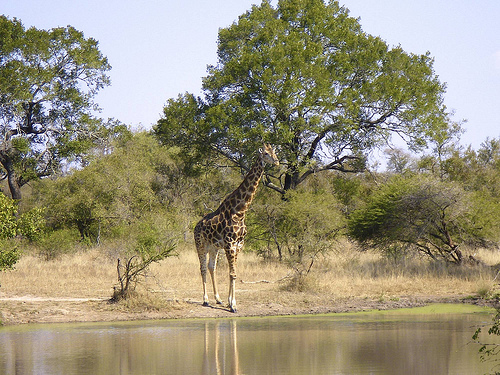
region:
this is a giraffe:
[150, 120, 312, 325]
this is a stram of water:
[0, 300, 498, 372]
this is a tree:
[369, 175, 497, 275]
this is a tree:
[97, 195, 193, 320]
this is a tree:
[157, 0, 464, 248]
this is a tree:
[251, 146, 334, 299]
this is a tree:
[343, 133, 498, 329]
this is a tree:
[0, 11, 138, 254]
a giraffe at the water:
[149, 96, 370, 346]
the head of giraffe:
[249, 146, 284, 178]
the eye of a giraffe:
[256, 147, 273, 162]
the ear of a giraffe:
[251, 140, 268, 162]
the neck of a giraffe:
[192, 161, 277, 237]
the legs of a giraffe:
[221, 230, 251, 303]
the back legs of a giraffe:
[184, 242, 236, 320]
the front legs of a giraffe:
[221, 234, 256, 314]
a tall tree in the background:
[210, 33, 430, 218]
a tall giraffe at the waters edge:
[175, 126, 337, 314]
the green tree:
[232, 52, 367, 134]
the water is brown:
[197, 330, 295, 372]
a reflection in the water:
[196, 323, 246, 373]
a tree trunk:
[7, 172, 30, 200]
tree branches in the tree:
[414, 215, 469, 261]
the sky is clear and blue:
[110, 50, 175, 95]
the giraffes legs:
[193, 264, 229, 305]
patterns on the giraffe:
[220, 208, 242, 241]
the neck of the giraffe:
[237, 170, 261, 207]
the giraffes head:
[257, 145, 287, 165]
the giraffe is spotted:
[194, 140, 284, 311]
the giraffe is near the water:
[198, 142, 278, 313]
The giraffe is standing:
[197, 137, 279, 310]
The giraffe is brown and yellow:
[193, 144, 277, 311]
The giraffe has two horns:
[258, 140, 283, 168]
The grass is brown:
[8, 232, 496, 319]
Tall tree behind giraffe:
[163, 6, 449, 213]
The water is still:
[3, 313, 491, 370]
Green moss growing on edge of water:
[5, 294, 492, 337]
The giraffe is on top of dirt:
[193, 141, 280, 315]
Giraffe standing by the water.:
[193, 142, 278, 314]